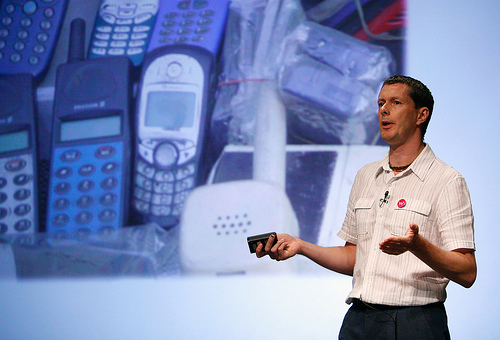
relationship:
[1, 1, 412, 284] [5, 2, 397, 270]
picture of cellphones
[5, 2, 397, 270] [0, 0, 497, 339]
cellphones on wall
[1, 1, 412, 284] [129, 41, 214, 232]
picture of cell phone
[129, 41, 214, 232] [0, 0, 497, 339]
cell phone on wall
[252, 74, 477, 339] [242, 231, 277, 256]
man holding phone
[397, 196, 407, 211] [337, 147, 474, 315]
logo on a shirt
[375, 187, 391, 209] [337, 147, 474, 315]
microphone on a shirt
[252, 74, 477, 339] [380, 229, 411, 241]
man with h palm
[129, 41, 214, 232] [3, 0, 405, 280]
cell phone projected on a screen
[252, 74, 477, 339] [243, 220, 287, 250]
man holding remote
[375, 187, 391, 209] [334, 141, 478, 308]
microphone attached to mans shirt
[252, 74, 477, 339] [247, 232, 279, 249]
man holding remote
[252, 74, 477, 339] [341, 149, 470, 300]
man wearing shirt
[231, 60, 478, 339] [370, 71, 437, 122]
man has short hair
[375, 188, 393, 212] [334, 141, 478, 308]
microphone coming out from shirt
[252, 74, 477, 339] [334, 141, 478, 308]
man has shirt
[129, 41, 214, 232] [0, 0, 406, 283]
cell phone on slide show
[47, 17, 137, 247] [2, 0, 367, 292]
cell phone on slide show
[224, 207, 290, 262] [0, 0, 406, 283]
phone on slide show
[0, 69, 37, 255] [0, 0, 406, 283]
cell phone on slide show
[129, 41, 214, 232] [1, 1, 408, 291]
cell phone on slide show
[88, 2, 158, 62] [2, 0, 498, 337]
cell phone on slide show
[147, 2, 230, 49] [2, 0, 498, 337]
cell phone on slide show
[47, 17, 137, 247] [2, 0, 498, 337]
cell phone on slide show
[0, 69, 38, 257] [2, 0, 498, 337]
cell phone on slide show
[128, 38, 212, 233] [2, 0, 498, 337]
cell phone on slide show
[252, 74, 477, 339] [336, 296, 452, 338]
man wears black slacks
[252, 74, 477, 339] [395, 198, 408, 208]
man wears logo